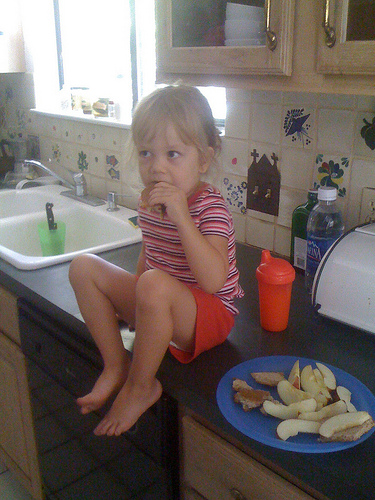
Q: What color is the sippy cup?
A: Orange.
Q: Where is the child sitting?
A: On a counter.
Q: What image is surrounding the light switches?
A: A church.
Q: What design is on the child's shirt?
A: Stripes.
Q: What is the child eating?
A: A sandwich.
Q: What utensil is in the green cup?
A: A knife.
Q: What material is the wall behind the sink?
A: Tile.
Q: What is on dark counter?
A: Blue plate.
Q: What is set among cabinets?
A: Black dishwasher.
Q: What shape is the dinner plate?
A: Round blue.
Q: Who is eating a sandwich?
A: A young child.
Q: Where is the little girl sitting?
A: On a counter.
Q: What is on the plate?
A: Bread and sliced apples.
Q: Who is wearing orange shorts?
A: The girl.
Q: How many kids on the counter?
A: One.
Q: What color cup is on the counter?
A: Orange.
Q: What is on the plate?
A: Apple slices.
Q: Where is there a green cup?
A: In the sink.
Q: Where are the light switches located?
A: On the wall behind the girl.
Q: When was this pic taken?
A: Daytime.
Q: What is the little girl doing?
A: Eating.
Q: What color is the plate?
A: Blue.